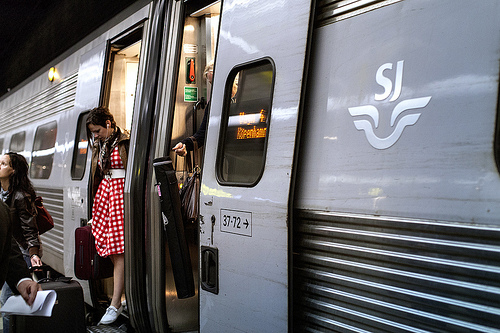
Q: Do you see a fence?
A: No, there are no fences.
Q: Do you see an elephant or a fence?
A: No, there are no fences or elephants.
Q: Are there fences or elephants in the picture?
A: No, there are no fences or elephants.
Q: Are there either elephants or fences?
A: No, there are no fences or elephants.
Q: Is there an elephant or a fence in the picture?
A: No, there are no fences or elephants.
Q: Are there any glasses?
A: No, there are no glasses.